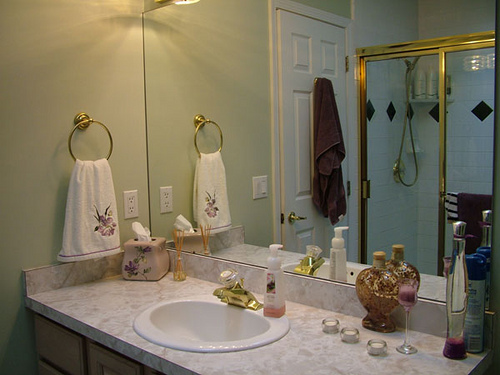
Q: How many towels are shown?
A: Two.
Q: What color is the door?
A: White.